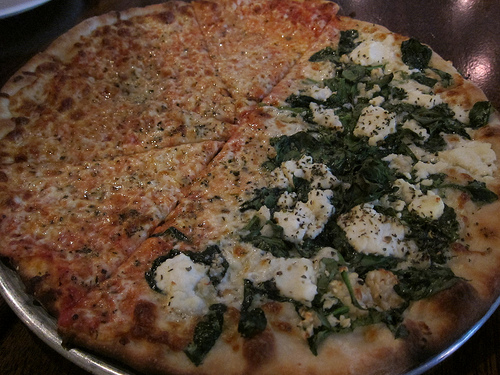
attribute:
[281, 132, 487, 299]
piece — garnished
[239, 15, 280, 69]
pizza — sliced, garnished, 8 slices, 4 cheese slices, halved, fresh out of oven, garliced, well done, cheese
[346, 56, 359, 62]
spinach — green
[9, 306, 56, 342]
pizza tray — round, silver, aluminum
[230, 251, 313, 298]
ricotta cheese — crumbled on pizza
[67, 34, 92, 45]
crust — burnt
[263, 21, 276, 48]
cheese — melted, on 4 slices, stuck on pizza tray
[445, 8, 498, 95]
reflection — from light